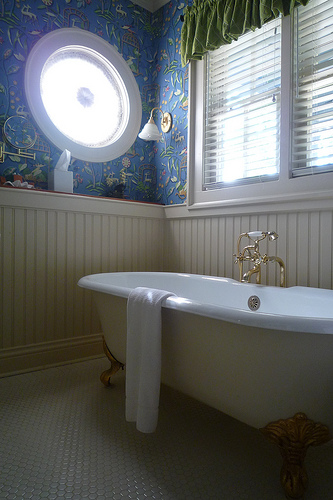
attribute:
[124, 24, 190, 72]
wallpaper — blue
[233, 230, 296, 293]
fixtures — gold, brass, golden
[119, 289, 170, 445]
towel — white, hanging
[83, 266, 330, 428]
tub — white, large, big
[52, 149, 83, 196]
tissues — white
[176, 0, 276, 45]
curtain — green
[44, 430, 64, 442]
tiles — hexagons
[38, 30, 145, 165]
window — round, circular, circle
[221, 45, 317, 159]
blinds — white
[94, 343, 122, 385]
claw — brass, gold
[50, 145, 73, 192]
tissue — white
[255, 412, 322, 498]
claws — brass, gold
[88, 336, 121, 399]
stand — gold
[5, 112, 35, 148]
mirror — round